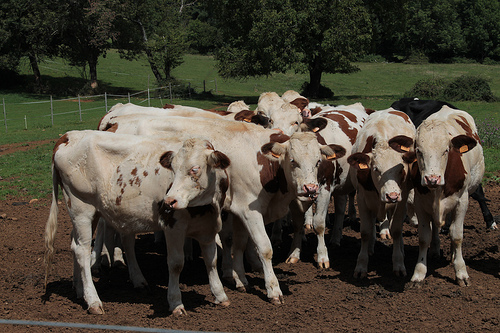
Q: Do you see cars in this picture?
A: No, there are no cars.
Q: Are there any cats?
A: No, there are no cats.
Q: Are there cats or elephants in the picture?
A: No, there are no cats or elephants.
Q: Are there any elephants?
A: No, there are no elephants.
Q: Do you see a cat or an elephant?
A: No, there are no elephants or cats.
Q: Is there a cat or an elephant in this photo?
A: No, there are no elephants or cats.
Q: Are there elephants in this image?
A: No, there are no elephants.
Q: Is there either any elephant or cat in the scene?
A: No, there are no elephants or cats.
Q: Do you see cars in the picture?
A: No, there are no cars.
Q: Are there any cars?
A: No, there are no cars.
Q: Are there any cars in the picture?
A: No, there are no cars.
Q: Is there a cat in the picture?
A: No, there are no cats.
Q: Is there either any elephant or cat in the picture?
A: No, there are no cats or elephants.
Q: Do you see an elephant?
A: No, there are no elephants.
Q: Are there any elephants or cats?
A: No, there are no elephants or cats.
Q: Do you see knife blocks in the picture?
A: No, there are no knife blocks.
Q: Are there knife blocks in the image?
A: No, there are no knife blocks.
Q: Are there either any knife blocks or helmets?
A: No, there are no knife blocks or helmets.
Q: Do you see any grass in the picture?
A: Yes, there is grass.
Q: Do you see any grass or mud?
A: Yes, there is grass.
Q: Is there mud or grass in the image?
A: Yes, there is grass.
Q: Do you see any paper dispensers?
A: No, there are no paper dispensers.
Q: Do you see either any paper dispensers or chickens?
A: No, there are no paper dispensers or chickens.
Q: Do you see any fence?
A: Yes, there is a fence.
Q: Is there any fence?
A: Yes, there is a fence.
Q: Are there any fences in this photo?
A: Yes, there is a fence.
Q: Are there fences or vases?
A: Yes, there is a fence.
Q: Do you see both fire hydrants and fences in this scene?
A: No, there is a fence but no fire hydrants.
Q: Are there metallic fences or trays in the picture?
A: Yes, there is a metal fence.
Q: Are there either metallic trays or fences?
A: Yes, there is a metal fence.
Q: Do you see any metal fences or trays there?
A: Yes, there is a metal fence.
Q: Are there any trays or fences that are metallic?
A: Yes, the fence is metallic.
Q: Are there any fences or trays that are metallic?
A: Yes, the fence is metallic.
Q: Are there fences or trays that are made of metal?
A: Yes, the fence is made of metal.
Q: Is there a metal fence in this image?
A: Yes, there is a metal fence.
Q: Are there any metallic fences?
A: Yes, there is a metal fence.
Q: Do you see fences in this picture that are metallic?
A: Yes, there is a fence that is metallic.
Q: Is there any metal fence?
A: Yes, there is a fence that is made of metal.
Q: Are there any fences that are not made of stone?
A: Yes, there is a fence that is made of metal.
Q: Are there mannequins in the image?
A: No, there are no mannequins.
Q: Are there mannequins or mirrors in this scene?
A: No, there are no mannequins or mirrors.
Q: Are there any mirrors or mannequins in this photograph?
A: No, there are no mannequins or mirrors.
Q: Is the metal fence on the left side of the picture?
A: Yes, the fence is on the left of the image.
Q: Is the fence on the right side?
A: No, the fence is on the left of the image.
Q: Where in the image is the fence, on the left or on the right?
A: The fence is on the left of the image.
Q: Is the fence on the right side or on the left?
A: The fence is on the left of the image.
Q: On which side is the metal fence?
A: The fence is on the left of the image.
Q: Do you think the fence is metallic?
A: Yes, the fence is metallic.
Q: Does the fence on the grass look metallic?
A: Yes, the fence is metallic.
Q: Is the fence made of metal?
A: Yes, the fence is made of metal.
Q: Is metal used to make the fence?
A: Yes, the fence is made of metal.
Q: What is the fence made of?
A: The fence is made of metal.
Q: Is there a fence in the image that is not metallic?
A: No, there is a fence but it is metallic.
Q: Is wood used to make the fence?
A: No, the fence is made of metal.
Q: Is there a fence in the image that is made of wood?
A: No, there is a fence but it is made of metal.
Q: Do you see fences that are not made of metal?
A: No, there is a fence but it is made of metal.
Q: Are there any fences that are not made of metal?
A: No, there is a fence but it is made of metal.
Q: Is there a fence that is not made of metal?
A: No, there is a fence but it is made of metal.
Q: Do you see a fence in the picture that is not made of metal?
A: No, there is a fence but it is made of metal.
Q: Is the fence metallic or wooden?
A: The fence is metallic.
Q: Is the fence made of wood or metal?
A: The fence is made of metal.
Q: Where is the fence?
A: The fence is on the grass.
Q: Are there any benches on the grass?
A: No, there is a fence on the grass.